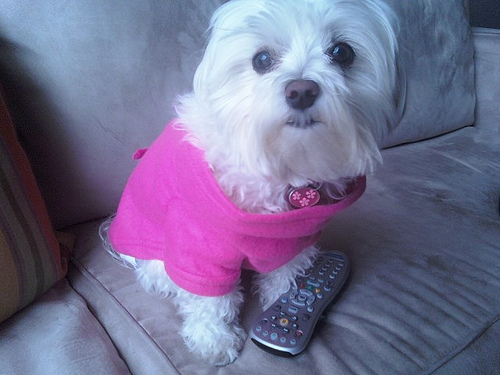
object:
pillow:
[4, 62, 70, 315]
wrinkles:
[400, 300, 421, 318]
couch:
[1, 0, 497, 375]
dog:
[110, 9, 406, 362]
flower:
[292, 191, 302, 200]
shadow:
[19, 81, 90, 272]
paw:
[173, 321, 251, 364]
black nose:
[284, 80, 322, 109]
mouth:
[286, 111, 323, 133]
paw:
[256, 283, 285, 309]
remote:
[241, 220, 369, 372]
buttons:
[298, 295, 306, 301]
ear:
[388, 60, 403, 83]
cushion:
[58, 128, 498, 375]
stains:
[418, 142, 487, 173]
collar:
[289, 185, 321, 212]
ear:
[195, 38, 238, 104]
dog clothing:
[87, 122, 372, 309]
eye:
[330, 42, 355, 67]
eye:
[252, 49, 272, 71]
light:
[260, 55, 271, 65]